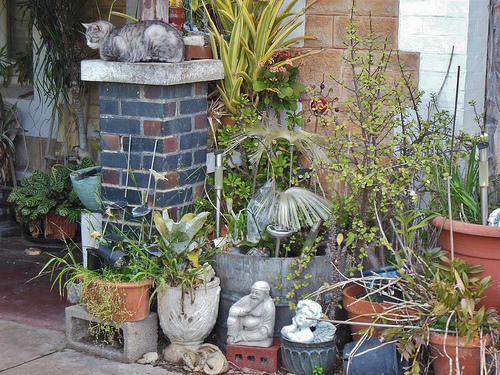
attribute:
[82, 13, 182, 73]
cat — sitting, gray, white, watching door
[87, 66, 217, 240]
pillar — red, black, brick, cement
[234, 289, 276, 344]
graden statue — an angel, white, buddah, small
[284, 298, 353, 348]
graden statue — concrete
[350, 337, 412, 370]
flower pot — empty, tan, on its side, blue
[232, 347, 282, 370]
brick — gray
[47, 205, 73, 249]
clay pot — red, red orange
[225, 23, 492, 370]
garden — unmaintained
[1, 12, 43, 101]
window — framed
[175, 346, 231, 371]
resting dragon — statue